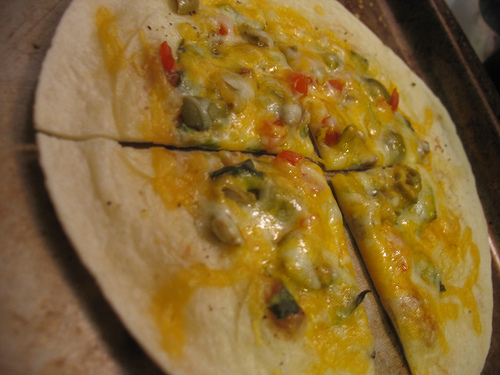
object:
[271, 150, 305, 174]
peppers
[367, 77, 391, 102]
peppers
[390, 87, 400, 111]
peppers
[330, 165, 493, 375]
ground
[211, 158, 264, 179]
cilantro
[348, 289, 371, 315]
cilantro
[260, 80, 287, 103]
cilantro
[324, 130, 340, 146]
tomato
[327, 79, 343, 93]
tomato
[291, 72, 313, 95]
red pepper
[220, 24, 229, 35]
red pepper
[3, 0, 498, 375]
grill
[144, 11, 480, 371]
glaze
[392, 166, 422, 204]
jalapeno slice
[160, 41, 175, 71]
pepper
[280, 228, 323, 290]
meat ball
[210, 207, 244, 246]
meat ball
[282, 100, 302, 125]
meat ball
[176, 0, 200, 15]
meat ball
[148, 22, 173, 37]
spots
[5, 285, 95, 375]
marks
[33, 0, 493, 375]
cheese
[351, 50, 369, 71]
vegetables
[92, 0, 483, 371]
sauce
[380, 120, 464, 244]
silver pan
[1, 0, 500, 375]
table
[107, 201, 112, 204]
fleck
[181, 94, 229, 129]
meat ball